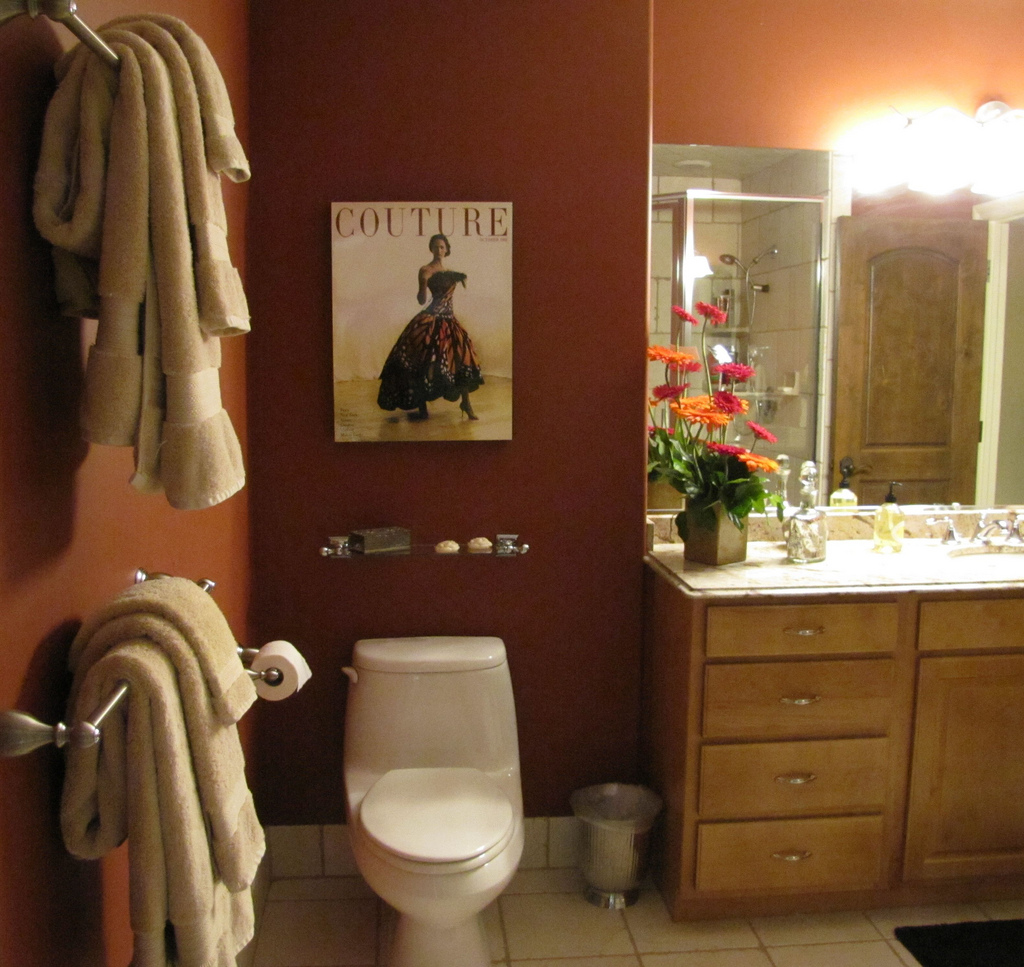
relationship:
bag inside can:
[582, 767, 652, 817] [569, 750, 658, 900]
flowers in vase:
[637, 286, 776, 509] [668, 489, 755, 569]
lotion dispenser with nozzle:
[868, 474, 918, 550] [879, 476, 906, 507]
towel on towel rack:
[30, 7, 253, 520] [2, 5, 121, 66]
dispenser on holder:
[250, 640, 311, 701] [227, 646, 280, 688]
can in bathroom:
[572, 775, 666, 922] [13, 1, 1016, 957]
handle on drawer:
[781, 682, 834, 717] [699, 652, 913, 750]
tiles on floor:
[509, 881, 862, 964] [255, 863, 1022, 957]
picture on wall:
[317, 179, 532, 452] [15, 1, 655, 963]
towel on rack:
[45, 555, 292, 964] [4, 570, 221, 789]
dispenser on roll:
[250, 640, 311, 701] [241, 624, 311, 717]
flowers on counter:
[639, 291, 797, 564] [640, 540, 1010, 607]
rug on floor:
[892, 899, 1020, 964] [253, 875, 1018, 964]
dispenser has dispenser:
[229, 641, 316, 700] [250, 640, 311, 701]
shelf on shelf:
[318, 544, 529, 557] [303, 540, 543, 571]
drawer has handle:
[693, 596, 916, 666] [765, 616, 833, 643]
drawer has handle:
[689, 655, 914, 740] [765, 678, 830, 718]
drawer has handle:
[693, 726, 901, 824] [771, 763, 817, 792]